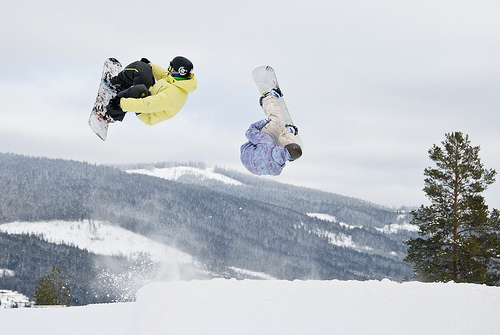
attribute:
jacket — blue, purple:
[238, 116, 291, 178]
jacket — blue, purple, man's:
[211, 133, 303, 174]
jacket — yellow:
[119, 61, 196, 127]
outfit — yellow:
[121, 58, 192, 120]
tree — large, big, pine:
[403, 122, 498, 280]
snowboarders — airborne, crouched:
[87, 55, 303, 177]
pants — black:
[98, 44, 160, 121]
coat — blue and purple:
[237, 113, 292, 183]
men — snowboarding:
[84, 52, 306, 181]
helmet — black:
[169, 55, 194, 77]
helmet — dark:
[280, 136, 303, 156]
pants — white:
[253, 92, 300, 147]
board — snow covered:
[252, 66, 294, 130]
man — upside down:
[102, 51, 200, 132]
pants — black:
[108, 60, 153, 121]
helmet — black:
[166, 50, 205, 82]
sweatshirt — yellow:
[117, 57, 194, 126]